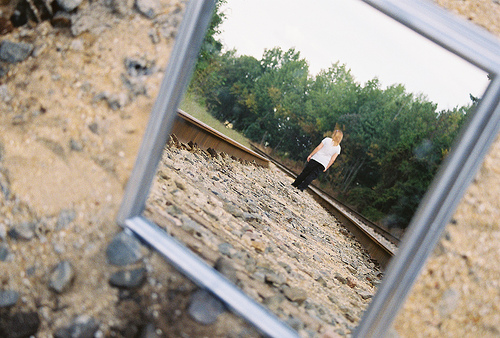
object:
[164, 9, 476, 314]
mirror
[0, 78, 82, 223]
ground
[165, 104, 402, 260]
tracks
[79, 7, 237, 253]
frame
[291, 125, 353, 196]
woman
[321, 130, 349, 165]
shirt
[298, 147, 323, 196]
pants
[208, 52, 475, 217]
trees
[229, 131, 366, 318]
rocks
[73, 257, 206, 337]
rocks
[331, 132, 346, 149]
hair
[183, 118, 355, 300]
ties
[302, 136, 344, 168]
arms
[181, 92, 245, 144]
grass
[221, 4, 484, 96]
sky